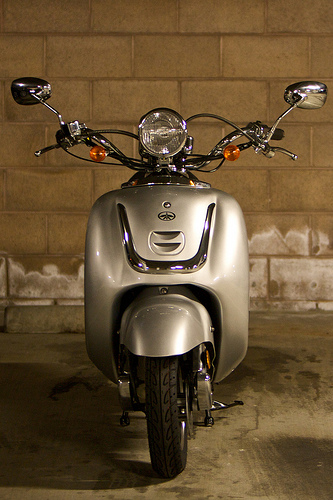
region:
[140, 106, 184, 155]
the big round headlight on a motorcycle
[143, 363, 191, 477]
a black rubber motorcycle tire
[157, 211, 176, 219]
the symbol of a motorcycle brand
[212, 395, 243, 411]
the stop pedal on a motorcycle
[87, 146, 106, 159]
a round yellow light on a motorcycle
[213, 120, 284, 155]
the left handle bar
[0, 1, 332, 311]
wall made of cinder blocks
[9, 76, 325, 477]
front of parked scooter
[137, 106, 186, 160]
round headlight of scooter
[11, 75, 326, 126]
backs of two mirrors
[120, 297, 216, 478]
fender over scooter tire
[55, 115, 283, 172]
handlebars on top of scooter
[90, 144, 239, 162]
two round orange turn signals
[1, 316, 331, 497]
cement surface with stains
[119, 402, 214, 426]
kickstand on cement surface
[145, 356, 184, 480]
treads in rubber tire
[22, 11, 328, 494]
this is a moped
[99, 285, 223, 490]
tire on the moped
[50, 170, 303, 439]
the moped is silver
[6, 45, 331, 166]
mirrors on the moped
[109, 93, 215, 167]
this is a headlight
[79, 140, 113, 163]
signal on the scooter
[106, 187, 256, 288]
silver trim on moped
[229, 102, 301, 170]
break on the scooter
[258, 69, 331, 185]
the mirror is silver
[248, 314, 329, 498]
stains on the concrete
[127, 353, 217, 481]
The front wheel of the scooter.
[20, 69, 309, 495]
The scooter is gray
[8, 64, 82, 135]
The left rear view mirror.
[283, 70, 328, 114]
The right rear view mirror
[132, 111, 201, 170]
The headlight on the scooter.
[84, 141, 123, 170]
The left orange light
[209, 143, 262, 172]
The right orange light.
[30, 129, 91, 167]
The left handle bar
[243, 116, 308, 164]
The right handle bar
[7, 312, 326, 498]
The ground is concrete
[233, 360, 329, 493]
the cement is dirty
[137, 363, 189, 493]
the tire is black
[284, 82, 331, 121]
the mirror is silver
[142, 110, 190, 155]
the light is circle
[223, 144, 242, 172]
the headlight is orange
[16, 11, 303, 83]
the wall is brick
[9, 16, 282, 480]
wall behind the bike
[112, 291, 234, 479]
wheel on the bike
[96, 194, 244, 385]
the bike is silver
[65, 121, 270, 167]
the handlebars are chrome